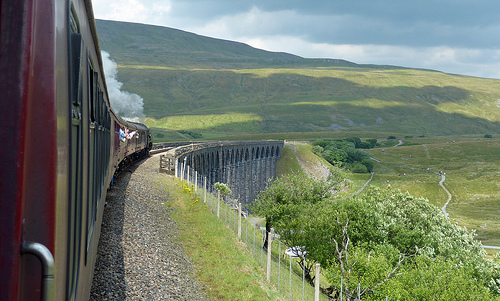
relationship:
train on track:
[20, 0, 156, 281] [1, 133, 278, 279]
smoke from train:
[101, 52, 152, 120] [20, 0, 156, 281]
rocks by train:
[118, 184, 180, 295] [20, 0, 156, 281]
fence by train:
[183, 159, 326, 288] [20, 0, 156, 281]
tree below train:
[255, 187, 325, 268] [20, 0, 156, 281]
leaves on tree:
[277, 191, 292, 208] [255, 187, 325, 268]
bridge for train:
[185, 130, 286, 209] [20, 0, 156, 281]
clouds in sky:
[166, 5, 329, 45] [94, 0, 499, 81]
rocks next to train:
[118, 184, 180, 295] [20, 0, 156, 281]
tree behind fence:
[255, 187, 325, 268] [183, 159, 326, 288]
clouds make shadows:
[166, 5, 329, 45] [157, 64, 456, 124]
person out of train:
[118, 123, 139, 148] [20, 0, 156, 281]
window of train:
[88, 70, 104, 132] [20, 0, 156, 281]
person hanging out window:
[118, 123, 139, 148] [88, 70, 104, 132]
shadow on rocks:
[85, 151, 151, 300] [118, 184, 180, 295]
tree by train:
[255, 187, 325, 268] [20, 0, 156, 281]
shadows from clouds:
[157, 64, 456, 124] [166, 5, 329, 45]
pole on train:
[29, 235, 59, 300] [20, 0, 156, 281]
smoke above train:
[101, 52, 152, 120] [20, 0, 156, 281]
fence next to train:
[183, 159, 326, 288] [20, 0, 156, 281]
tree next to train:
[255, 187, 325, 268] [20, 0, 156, 281]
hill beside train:
[97, 19, 391, 131] [20, 0, 156, 281]